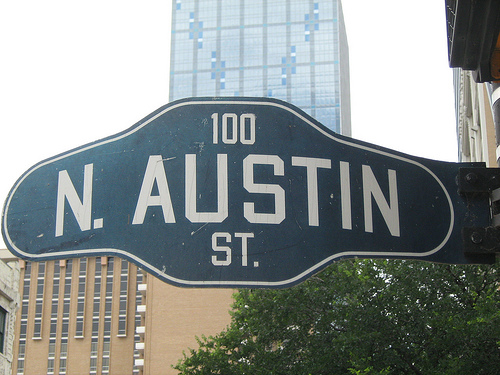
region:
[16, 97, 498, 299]
the sign says N. austin st.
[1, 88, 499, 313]
the sign is black and white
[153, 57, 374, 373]
the building behind the sign is tall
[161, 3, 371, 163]
the building is glass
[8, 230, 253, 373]
the building is brown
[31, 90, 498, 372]
a tree behind the sign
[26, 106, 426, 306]
the sign has white letters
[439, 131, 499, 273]
the sign is held up by bolts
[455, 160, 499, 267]
the bolts are black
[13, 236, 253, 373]
the brown building has windows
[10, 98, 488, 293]
a street sign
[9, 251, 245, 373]
a red brick building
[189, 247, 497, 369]
a green leafy tree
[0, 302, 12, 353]
a window in a concrete building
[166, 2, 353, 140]
a tall gass and concrete building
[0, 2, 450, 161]
a white cloudy sky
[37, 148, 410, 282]
white letters on a street sign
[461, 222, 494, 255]
a bolt attaching a street sign to a post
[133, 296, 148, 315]
a balcony off the side of a brick building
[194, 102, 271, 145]
white numbers on a street sign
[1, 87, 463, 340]
street sign for austin street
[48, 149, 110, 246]
white letters on a street sign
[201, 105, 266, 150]
numbers on a street sign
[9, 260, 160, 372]
lots of windows on a building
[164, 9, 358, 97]
skyscraper with lots of windows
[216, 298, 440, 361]
green tree growing in the city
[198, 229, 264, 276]
abbreviation for street on a sign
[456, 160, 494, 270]
bolts on a street sign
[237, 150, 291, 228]
white letter ess on a sign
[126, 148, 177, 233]
white letter a on a sign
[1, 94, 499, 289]
black and white street sign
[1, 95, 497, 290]
street sign reading 100 N. Austin St.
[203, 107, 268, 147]
white text on a street sign reading 100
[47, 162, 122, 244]
bold white text on a street sign reading N.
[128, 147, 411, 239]
bold white text on a street sign reading Austin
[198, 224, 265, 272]
white text on a street sign reading ST.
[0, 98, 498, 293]
street sign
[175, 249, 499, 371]
a green tree behind a street sign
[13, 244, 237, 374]
brown building with lots of windows on it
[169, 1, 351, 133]
the top of a very tall building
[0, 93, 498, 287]
a sign on a building.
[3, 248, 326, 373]
a multi story building.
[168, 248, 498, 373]
a tall leafy green tree.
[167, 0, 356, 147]
a tall multi story building.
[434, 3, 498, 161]
a multi story building.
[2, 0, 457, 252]
a gray cloudy sky.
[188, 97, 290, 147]
the number 100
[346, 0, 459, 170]
a section of gray sky.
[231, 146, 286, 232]
the letter S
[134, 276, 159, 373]
a row of windows on a building.